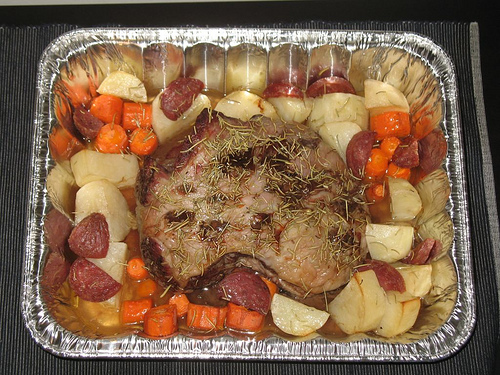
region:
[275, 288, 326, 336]
potatoe in a pan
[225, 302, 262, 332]
carrot in a pan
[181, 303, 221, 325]
carrot in a pan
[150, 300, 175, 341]
carrot in a pan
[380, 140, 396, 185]
carrot in a pan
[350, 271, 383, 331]
potatoe in a pan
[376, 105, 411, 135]
carrot in a pan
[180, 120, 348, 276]
roast in a pan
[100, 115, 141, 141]
carrots in a pan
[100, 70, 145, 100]
potatoe in a pan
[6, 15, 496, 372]
roast sitting on a hot pad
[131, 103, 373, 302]
the meat of the pot roast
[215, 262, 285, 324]
chopped up sausage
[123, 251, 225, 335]
orange carrots in the pot roast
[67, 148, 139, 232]
two white potatoes in pot roast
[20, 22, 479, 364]
aluminum container for the pot roast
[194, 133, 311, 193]
green seed like spices on the pot roast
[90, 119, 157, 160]
two orange sliced carrots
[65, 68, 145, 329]
vegetables and meat chopped up in roast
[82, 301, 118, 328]
broth made by cooking roast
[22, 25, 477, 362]
tin foil container of food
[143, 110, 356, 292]
piece of meat covered in herbs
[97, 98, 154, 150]
pieces of cut carrots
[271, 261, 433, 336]
chunks of white potato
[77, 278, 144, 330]
liquid in bottom of pan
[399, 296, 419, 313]
cooked edge of potato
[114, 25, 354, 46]
light reflection on foil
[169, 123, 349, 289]
fat on side of meat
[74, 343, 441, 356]
creases in tin foil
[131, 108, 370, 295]
one cooked piece of meat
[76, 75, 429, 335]
piece of meat surrounded by vegetables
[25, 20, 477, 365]
pan of meat and potatoes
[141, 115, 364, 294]
cooked meat sprinkled with rosemary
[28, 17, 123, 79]
rounded corner of aluminum pan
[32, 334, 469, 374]
shiny edge of aluminum foil pan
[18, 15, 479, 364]
full rectangular foil pan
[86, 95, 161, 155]
four chunks of cooked carrot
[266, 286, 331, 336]
semi-circular piece of white potato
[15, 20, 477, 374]
shiny pan of food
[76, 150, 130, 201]
sliced white potatoes in pan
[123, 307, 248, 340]
sliced carrots in pan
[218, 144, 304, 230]
herbs on top of beef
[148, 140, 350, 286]
beef roasted in the pan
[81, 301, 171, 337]
juices from the beef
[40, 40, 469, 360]
aluminum pan holding food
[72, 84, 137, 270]
mixed veggies in pan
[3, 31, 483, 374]
mat under the aluminum pan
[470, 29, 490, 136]
silver strip on mat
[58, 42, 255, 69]
top of an aluminum pan